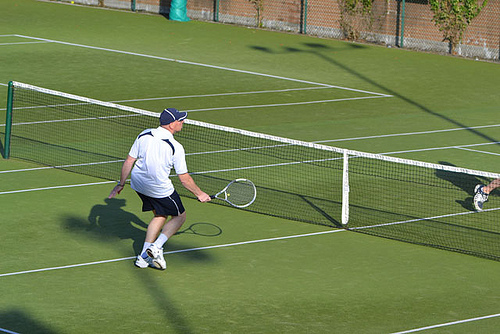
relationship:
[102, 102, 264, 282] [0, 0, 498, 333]
man on court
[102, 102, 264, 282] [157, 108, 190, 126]
man wearing hat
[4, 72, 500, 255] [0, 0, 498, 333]
net on court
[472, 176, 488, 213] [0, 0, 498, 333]
shoe on court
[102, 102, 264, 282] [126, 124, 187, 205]
man in shirt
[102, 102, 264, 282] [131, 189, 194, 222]
man in shorts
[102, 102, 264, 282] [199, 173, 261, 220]
man holding racket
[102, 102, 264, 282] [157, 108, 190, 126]
man in hat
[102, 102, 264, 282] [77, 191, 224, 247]
man casting shadow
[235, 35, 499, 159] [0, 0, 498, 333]
pole on court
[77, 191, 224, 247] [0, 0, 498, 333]
shadow on court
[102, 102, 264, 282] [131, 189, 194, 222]
man wearing shorts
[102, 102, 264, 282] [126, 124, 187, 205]
man wearing shirt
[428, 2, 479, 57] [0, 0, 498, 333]
tree on court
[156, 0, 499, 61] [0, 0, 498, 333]
wall behind court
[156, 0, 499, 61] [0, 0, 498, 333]
wall near court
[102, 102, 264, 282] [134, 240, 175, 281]
man in shoes